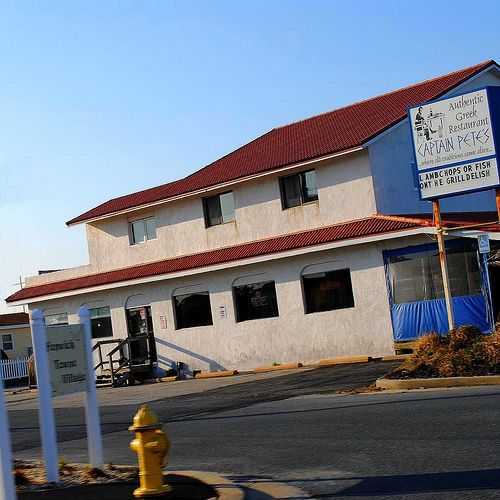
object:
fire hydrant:
[128, 403, 172, 497]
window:
[299, 259, 357, 315]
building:
[5, 58, 500, 378]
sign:
[408, 84, 489, 132]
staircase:
[90, 332, 155, 387]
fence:
[0, 353, 30, 380]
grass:
[395, 318, 500, 375]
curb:
[375, 375, 500, 391]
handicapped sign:
[159, 315, 167, 329]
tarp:
[381, 235, 496, 343]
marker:
[193, 369, 237, 379]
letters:
[417, 161, 494, 190]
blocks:
[135, 354, 407, 386]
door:
[123, 305, 157, 365]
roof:
[64, 61, 500, 228]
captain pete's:
[418, 128, 491, 156]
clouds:
[3, 193, 67, 238]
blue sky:
[0, 0, 190, 124]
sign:
[42, 336, 86, 387]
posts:
[30, 307, 106, 481]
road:
[224, 386, 500, 499]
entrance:
[91, 303, 160, 388]